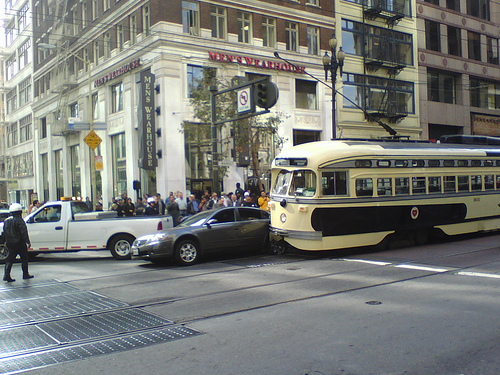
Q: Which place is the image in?
A: It is at the street.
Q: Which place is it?
A: It is a street.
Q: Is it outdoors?
A: Yes, it is outdoors.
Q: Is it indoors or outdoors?
A: It is outdoors.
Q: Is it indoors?
A: No, it is outdoors.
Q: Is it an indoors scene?
A: No, it is outdoors.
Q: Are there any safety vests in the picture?
A: No, there are no safety vests.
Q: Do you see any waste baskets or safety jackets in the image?
A: No, there are no safety jackets or waste baskets.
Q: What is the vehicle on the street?
A: The vehicle is a car.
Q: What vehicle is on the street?
A: The vehicle is a car.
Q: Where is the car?
A: The car is on the street.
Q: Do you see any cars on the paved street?
A: Yes, there is a car on the street.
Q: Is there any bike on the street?
A: No, there is a car on the street.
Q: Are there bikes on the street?
A: No, there is a car on the street.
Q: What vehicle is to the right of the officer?
A: The vehicle is a car.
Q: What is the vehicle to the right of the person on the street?
A: The vehicle is a car.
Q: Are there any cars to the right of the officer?
A: Yes, there is a car to the right of the officer.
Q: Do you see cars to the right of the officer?
A: Yes, there is a car to the right of the officer.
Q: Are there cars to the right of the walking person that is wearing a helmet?
A: Yes, there is a car to the right of the officer.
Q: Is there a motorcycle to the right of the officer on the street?
A: No, there is a car to the right of the officer.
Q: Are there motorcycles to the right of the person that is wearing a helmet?
A: No, there is a car to the right of the officer.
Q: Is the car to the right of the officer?
A: Yes, the car is to the right of the officer.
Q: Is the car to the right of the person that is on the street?
A: Yes, the car is to the right of the officer.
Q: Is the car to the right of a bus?
A: No, the car is to the right of the officer.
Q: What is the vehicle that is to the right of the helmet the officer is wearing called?
A: The vehicle is a car.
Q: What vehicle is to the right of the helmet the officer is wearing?
A: The vehicle is a car.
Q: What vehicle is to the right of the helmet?
A: The vehicle is a car.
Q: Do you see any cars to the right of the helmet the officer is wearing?
A: Yes, there is a car to the right of the helmet.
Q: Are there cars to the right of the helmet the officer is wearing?
A: Yes, there is a car to the right of the helmet.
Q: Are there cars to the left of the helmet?
A: No, the car is to the right of the helmet.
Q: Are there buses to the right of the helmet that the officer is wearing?
A: No, there is a car to the right of the helmet.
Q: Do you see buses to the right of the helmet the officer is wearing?
A: No, there is a car to the right of the helmet.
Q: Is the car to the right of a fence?
A: No, the car is to the right of a helmet.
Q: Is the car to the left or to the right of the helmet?
A: The car is to the right of the helmet.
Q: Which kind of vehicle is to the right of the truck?
A: The vehicle is a car.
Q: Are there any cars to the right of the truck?
A: Yes, there is a car to the right of the truck.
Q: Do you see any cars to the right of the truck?
A: Yes, there is a car to the right of the truck.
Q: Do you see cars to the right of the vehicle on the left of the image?
A: Yes, there is a car to the right of the truck.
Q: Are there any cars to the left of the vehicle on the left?
A: No, the car is to the right of the truck.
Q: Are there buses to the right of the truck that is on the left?
A: No, there is a car to the right of the truck.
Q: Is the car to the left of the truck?
A: No, the car is to the right of the truck.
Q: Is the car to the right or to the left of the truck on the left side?
A: The car is to the right of the truck.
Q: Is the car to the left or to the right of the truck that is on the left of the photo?
A: The car is to the right of the truck.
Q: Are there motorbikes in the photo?
A: No, there are no motorbikes.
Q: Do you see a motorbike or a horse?
A: No, there are no motorcycles or horses.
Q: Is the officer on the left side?
A: Yes, the officer is on the left of the image.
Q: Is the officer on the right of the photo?
A: No, the officer is on the left of the image.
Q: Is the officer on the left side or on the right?
A: The officer is on the left of the image.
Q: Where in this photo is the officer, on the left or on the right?
A: The officer is on the left of the image.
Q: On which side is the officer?
A: The officer is on the left of the image.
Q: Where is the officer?
A: The officer is on the street.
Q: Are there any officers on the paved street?
A: Yes, there is an officer on the street.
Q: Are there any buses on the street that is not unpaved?
A: No, there is an officer on the street.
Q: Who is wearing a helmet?
A: The officer is wearing a helmet.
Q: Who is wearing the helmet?
A: The officer is wearing a helmet.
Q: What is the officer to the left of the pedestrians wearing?
A: The officer is wearing a helmet.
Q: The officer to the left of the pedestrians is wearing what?
A: The officer is wearing a helmet.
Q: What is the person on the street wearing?
A: The officer is wearing a helmet.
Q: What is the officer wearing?
A: The officer is wearing a helmet.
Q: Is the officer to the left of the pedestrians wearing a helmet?
A: Yes, the officer is wearing a helmet.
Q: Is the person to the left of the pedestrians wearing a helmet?
A: Yes, the officer is wearing a helmet.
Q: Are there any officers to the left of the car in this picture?
A: Yes, there is an officer to the left of the car.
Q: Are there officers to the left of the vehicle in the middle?
A: Yes, there is an officer to the left of the car.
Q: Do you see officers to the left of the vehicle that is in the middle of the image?
A: Yes, there is an officer to the left of the car.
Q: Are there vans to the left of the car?
A: No, there is an officer to the left of the car.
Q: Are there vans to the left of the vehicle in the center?
A: No, there is an officer to the left of the car.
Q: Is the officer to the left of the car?
A: Yes, the officer is to the left of the car.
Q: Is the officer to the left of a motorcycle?
A: No, the officer is to the left of the car.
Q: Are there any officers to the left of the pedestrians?
A: Yes, there is an officer to the left of the pedestrians.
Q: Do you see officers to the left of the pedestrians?
A: Yes, there is an officer to the left of the pedestrians.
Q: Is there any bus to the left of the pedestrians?
A: No, there is an officer to the left of the pedestrians.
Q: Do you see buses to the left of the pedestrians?
A: No, there is an officer to the left of the pedestrians.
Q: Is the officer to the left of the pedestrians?
A: Yes, the officer is to the left of the pedestrians.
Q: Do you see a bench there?
A: No, there are no benches.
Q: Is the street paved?
A: Yes, the street is paved.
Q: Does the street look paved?
A: Yes, the street is paved.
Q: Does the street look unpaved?
A: No, the street is paved.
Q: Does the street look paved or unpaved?
A: The street is paved.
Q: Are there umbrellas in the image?
A: No, there are no umbrellas.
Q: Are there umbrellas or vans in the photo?
A: No, there are no umbrellas or vans.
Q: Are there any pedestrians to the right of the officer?
A: Yes, there are pedestrians to the right of the officer.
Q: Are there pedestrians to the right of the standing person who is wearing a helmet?
A: Yes, there are pedestrians to the right of the officer.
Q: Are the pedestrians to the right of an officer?
A: Yes, the pedestrians are to the right of an officer.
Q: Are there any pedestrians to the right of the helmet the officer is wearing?
A: Yes, there are pedestrians to the right of the helmet.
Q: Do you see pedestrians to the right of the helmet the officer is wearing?
A: Yes, there are pedestrians to the right of the helmet.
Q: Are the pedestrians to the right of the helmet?
A: Yes, the pedestrians are to the right of the helmet.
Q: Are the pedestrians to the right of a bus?
A: No, the pedestrians are to the right of the helmet.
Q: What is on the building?
A: The sign is on the building.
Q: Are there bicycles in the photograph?
A: No, there are no bicycles.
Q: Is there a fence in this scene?
A: No, there are no fences.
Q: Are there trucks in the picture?
A: Yes, there is a truck.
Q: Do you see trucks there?
A: Yes, there is a truck.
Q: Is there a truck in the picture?
A: Yes, there is a truck.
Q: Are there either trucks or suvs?
A: Yes, there is a truck.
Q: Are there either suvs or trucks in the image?
A: Yes, there is a truck.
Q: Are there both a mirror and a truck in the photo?
A: Yes, there are both a truck and a mirror.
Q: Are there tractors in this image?
A: No, there are no tractors.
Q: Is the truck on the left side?
A: Yes, the truck is on the left of the image.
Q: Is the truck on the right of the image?
A: No, the truck is on the left of the image.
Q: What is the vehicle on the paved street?
A: The vehicle is a truck.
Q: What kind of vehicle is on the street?
A: The vehicle is a truck.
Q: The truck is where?
A: The truck is on the street.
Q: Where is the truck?
A: The truck is on the street.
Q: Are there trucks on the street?
A: Yes, there is a truck on the street.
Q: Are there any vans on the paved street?
A: No, there is a truck on the street.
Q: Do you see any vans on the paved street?
A: No, there is a truck on the street.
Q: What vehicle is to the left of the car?
A: The vehicle is a truck.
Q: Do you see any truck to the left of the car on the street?
A: Yes, there is a truck to the left of the car.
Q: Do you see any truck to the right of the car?
A: No, the truck is to the left of the car.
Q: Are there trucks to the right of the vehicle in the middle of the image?
A: No, the truck is to the left of the car.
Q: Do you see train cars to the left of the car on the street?
A: No, there is a truck to the left of the car.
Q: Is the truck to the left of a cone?
A: No, the truck is to the left of the car.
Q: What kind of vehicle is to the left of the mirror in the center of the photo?
A: The vehicle is a truck.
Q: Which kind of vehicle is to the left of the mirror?
A: The vehicle is a truck.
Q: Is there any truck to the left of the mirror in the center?
A: Yes, there is a truck to the left of the mirror.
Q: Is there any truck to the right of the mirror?
A: No, the truck is to the left of the mirror.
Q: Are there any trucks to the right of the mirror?
A: No, the truck is to the left of the mirror.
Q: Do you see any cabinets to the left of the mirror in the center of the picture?
A: No, there is a truck to the left of the mirror.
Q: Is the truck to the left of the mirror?
A: Yes, the truck is to the left of the mirror.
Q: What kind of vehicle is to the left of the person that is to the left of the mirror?
A: The vehicle is a truck.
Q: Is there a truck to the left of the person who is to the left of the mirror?
A: Yes, there is a truck to the left of the person.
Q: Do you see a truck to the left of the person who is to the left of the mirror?
A: Yes, there is a truck to the left of the person.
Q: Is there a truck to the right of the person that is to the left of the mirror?
A: No, the truck is to the left of the person.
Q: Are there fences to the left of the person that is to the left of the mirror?
A: No, there is a truck to the left of the person.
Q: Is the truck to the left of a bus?
A: No, the truck is to the left of the person.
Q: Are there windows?
A: Yes, there are windows.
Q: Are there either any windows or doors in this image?
A: Yes, there are windows.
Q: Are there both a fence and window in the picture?
A: No, there are windows but no fences.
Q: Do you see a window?
A: Yes, there are windows.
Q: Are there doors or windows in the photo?
A: Yes, there are windows.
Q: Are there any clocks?
A: No, there are no clocks.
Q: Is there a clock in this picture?
A: No, there are no clocks.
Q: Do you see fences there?
A: No, there are no fences.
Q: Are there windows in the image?
A: Yes, there is a window.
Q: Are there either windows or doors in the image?
A: Yes, there is a window.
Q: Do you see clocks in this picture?
A: No, there are no clocks.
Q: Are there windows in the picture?
A: Yes, there is a window.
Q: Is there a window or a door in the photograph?
A: Yes, there is a window.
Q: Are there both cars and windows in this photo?
A: Yes, there are both a window and a car.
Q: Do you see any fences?
A: No, there are no fences.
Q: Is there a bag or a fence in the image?
A: No, there are no fences or bags.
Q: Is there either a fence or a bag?
A: No, there are no fences or bags.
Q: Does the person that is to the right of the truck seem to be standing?
A: Yes, the person is standing.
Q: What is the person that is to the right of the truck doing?
A: The person is standing.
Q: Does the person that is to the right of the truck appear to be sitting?
A: No, the person is standing.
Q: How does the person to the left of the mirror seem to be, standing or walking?
A: The person is standing.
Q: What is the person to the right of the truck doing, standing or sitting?
A: The person is standing.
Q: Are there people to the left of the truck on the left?
A: No, the person is to the right of the truck.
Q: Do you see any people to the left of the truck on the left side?
A: No, the person is to the right of the truck.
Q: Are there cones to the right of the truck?
A: No, there is a person to the right of the truck.